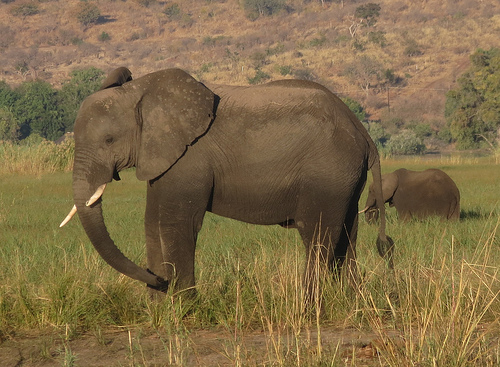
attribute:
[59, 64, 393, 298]
elephant — grey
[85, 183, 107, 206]
tusk — white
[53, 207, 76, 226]
tusk — white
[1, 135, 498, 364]
grass — tall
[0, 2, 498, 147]
hillside — brown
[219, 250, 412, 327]
grass — green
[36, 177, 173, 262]
field — grassy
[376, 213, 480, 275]
field — grassy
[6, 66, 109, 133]
trees — dark green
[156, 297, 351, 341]
dirt — brown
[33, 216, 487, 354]
field — large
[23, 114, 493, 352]
field — large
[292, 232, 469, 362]
grass — high, green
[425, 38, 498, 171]
tree — large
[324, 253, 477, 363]
grass — dry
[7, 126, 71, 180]
bush — thick, light green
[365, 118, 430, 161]
bush — large, light green